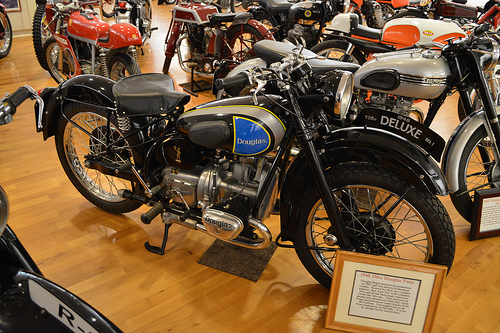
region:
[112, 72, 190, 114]
Gray seat of a Douglas motorbike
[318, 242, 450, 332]
Picture of writing in a wooden frame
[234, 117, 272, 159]
Blue black and yellow Douglas logo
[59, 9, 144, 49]
Shiny orange body of motocycle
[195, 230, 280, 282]
Small rug on the ground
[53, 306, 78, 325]
Black letter R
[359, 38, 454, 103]
Silver gas tank of motor bike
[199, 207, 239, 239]
Silver part of motorcycle that says Douglas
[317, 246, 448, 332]
Wooden framed photo with writing in it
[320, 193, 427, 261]
silver spokes in the wheel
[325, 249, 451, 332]
Light brown framed picture with writing on it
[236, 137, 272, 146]
Douglas written in yellow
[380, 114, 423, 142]
Deluxe written in gray writing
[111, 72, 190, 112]
Gray motorcycle seat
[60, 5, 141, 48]
Shiny orange motorcycle body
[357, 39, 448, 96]
Silver and black gas tank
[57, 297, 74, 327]
Black letter R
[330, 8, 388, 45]
Seat on a motorcycle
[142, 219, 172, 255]
black kickstand for motorcycle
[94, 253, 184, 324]
Wooden floor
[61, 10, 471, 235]
these are motorcycles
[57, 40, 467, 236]
the motorcycles are big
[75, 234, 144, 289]
this is the floor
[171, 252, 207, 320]
the floor is made of polished wood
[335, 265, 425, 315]
this is a certificate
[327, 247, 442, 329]
the certificate is framed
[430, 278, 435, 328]
the frame is wooden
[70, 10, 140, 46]
the motorcycle is red in color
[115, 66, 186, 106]
the seat is big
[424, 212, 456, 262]
the tire is black in color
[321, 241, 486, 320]
Sign by a motorcycle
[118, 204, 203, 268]
kickstand on a motorcycle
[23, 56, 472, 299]
Black and silver motorcycle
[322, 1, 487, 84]
Orange and white motorcycle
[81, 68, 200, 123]
Black motorcycle seat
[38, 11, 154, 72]
Orange motorcycle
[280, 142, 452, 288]
Black motorcycle tire on the front of a motorcycle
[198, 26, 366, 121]
Handle bars on a motorcycle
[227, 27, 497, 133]
Silver colored motorcycle with gray seat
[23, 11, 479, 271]
a group of motorcycles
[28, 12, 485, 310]
motorcycles displayed on wooden platform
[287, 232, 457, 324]
red and black text framed in wood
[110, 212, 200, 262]
kickstand lowered onto floor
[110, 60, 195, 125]
grey seat with lightly raised edge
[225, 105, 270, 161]
blue panel with identifying name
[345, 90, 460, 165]
curved sign attached to front wheel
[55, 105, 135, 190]
metal spokes and rim inside tire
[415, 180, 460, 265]
triangular pattern on treads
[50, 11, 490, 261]
motorcycles displayed in circular rows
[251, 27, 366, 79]
long and flat seat of motorcycle